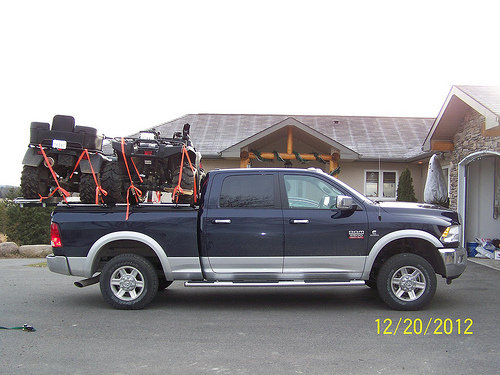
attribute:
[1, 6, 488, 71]
clouds — white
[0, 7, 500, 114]
sky — blue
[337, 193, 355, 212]
mirror — side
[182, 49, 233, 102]
clouds — white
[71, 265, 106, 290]
exhaust pipe — long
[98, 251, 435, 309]
tires — black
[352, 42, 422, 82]
clouds — white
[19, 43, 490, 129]
sky — blue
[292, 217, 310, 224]
handle — Silver door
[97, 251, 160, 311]
wheel — rear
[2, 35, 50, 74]
clouds — white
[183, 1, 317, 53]
sky — blue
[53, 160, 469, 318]
truck — black, blue, dark blue, pick up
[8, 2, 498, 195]
clouds — white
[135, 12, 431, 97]
sky — blue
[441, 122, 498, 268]
garage — stones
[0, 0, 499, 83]
sky — blue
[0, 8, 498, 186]
sky — blue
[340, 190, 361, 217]
mirror — Side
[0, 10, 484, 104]
sky — blue